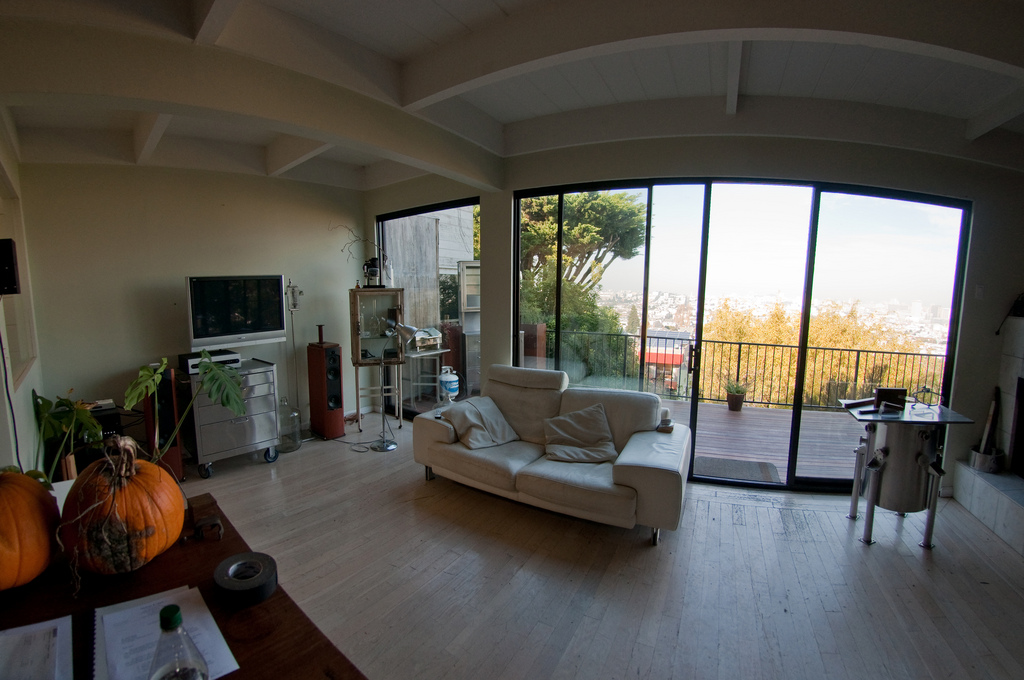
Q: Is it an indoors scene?
A: Yes, it is indoors.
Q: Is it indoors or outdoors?
A: It is indoors.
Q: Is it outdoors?
A: No, it is indoors.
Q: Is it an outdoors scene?
A: No, it is indoors.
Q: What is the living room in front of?
A: The living room is in front of the balcony.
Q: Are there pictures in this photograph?
A: No, there are no pictures.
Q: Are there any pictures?
A: No, there are no pictures.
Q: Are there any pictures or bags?
A: No, there are no pictures or bags.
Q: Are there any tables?
A: Yes, there is a table.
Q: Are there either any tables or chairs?
A: Yes, there is a table.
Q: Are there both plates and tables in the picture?
A: No, there is a table but no plates.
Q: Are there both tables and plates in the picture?
A: No, there is a table but no plates.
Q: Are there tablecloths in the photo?
A: No, there are no tablecloths.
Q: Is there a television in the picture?
A: Yes, there is a television.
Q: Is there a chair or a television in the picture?
A: Yes, there is a television.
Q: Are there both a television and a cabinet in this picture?
A: Yes, there are both a television and a cabinet.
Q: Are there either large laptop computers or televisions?
A: Yes, there is a large television.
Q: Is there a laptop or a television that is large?
A: Yes, the television is large.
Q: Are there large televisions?
A: Yes, there is a large television.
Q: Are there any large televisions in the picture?
A: Yes, there is a large television.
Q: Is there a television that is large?
A: Yes, there is a television that is large.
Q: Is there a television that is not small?
A: Yes, there is a large television.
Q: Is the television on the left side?
A: Yes, the television is on the left of the image.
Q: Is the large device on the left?
A: Yes, the television is on the left of the image.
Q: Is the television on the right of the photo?
A: No, the television is on the left of the image.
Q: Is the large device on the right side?
A: No, the television is on the left of the image.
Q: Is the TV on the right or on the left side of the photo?
A: The TV is on the left of the image.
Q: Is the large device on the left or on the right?
A: The TV is on the left of the image.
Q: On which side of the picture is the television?
A: The television is on the left of the image.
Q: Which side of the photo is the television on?
A: The television is on the left of the image.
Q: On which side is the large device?
A: The television is on the left of the image.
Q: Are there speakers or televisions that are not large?
A: No, there is a television but it is large.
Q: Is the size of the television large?
A: Yes, the television is large.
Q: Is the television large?
A: Yes, the television is large.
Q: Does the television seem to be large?
A: Yes, the television is large.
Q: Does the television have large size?
A: Yes, the television is large.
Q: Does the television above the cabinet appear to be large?
A: Yes, the TV is large.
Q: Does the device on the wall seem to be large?
A: Yes, the TV is large.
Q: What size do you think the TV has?
A: The TV has large size.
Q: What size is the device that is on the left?
A: The TV is large.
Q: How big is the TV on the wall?
A: The TV is large.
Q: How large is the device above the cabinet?
A: The TV is large.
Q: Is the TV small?
A: No, the TV is large.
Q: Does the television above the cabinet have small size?
A: No, the TV is large.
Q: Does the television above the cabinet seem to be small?
A: No, the TV is large.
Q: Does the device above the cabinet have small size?
A: No, the TV is large.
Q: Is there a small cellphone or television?
A: No, there is a television but it is large.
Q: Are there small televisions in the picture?
A: No, there is a television but it is large.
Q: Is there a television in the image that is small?
A: No, there is a television but it is large.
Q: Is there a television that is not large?
A: No, there is a television but it is large.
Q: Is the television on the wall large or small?
A: The TV is large.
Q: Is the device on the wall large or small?
A: The TV is large.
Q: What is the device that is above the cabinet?
A: The device is a television.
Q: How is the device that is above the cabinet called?
A: The device is a television.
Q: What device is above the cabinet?
A: The device is a television.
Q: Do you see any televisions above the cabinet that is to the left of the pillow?
A: Yes, there is a television above the cabinet.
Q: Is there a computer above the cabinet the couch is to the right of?
A: No, there is a television above the cabinet.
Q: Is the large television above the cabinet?
A: Yes, the television is above the cabinet.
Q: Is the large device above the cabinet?
A: Yes, the television is above the cabinet.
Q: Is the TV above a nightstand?
A: No, the TV is above the cabinet.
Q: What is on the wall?
A: The TV is on the wall.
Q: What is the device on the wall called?
A: The device is a television.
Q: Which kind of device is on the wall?
A: The device is a television.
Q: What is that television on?
A: The television is on the wall.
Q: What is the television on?
A: The television is on the wall.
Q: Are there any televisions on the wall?
A: Yes, there is a television on the wall.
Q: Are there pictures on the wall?
A: No, there is a television on the wall.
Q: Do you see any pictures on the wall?
A: No, there is a television on the wall.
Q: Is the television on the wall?
A: Yes, the television is on the wall.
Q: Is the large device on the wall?
A: Yes, the television is on the wall.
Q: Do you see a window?
A: Yes, there is a window.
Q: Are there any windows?
A: Yes, there is a window.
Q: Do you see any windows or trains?
A: Yes, there is a window.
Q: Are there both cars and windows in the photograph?
A: No, there is a window but no cars.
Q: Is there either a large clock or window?
A: Yes, there is a large window.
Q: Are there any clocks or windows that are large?
A: Yes, the window is large.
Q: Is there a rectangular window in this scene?
A: Yes, there is a rectangular window.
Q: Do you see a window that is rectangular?
A: Yes, there is a rectangular window.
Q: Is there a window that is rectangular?
A: Yes, there is a window that is rectangular.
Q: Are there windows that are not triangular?
A: Yes, there is a rectangular window.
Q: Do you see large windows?
A: Yes, there is a large window.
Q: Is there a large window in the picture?
A: Yes, there is a large window.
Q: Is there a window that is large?
A: Yes, there is a window that is large.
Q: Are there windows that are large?
A: Yes, there is a window that is large.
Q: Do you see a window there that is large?
A: Yes, there is a window that is large.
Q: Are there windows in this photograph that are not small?
A: Yes, there is a large window.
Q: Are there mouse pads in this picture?
A: No, there are no mouse pads.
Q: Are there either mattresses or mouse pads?
A: No, there are no mouse pads or mattresses.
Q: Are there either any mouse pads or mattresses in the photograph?
A: No, there are no mouse pads or mattresses.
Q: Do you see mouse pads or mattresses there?
A: No, there are no mouse pads or mattresses.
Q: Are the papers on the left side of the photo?
A: Yes, the papers are on the left of the image.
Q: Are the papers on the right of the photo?
A: No, the papers are on the left of the image.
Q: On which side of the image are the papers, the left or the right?
A: The papers are on the left of the image.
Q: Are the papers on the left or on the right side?
A: The papers are on the left of the image.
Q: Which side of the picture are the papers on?
A: The papers are on the left of the image.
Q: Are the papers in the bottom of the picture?
A: Yes, the papers are in the bottom of the image.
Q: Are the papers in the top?
A: No, the papers are in the bottom of the image.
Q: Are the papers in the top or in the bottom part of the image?
A: The papers are in the bottom of the image.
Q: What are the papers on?
A: The papers are on the table.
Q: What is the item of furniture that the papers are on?
A: The piece of furniture is a table.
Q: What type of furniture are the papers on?
A: The papers are on the table.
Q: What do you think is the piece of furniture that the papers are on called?
A: The piece of furniture is a table.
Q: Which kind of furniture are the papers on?
A: The papers are on the table.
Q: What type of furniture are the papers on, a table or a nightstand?
A: The papers are on a table.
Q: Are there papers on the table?
A: Yes, there are papers on the table.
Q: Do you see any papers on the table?
A: Yes, there are papers on the table.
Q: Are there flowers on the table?
A: No, there are papers on the table.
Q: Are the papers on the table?
A: Yes, the papers are on the table.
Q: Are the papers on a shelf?
A: No, the papers are on the table.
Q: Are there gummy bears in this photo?
A: No, there are no gummy bears.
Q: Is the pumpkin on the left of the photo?
A: Yes, the pumpkin is on the left of the image.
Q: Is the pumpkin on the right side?
A: No, the pumpkin is on the left of the image.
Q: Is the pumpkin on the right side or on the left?
A: The pumpkin is on the left of the image.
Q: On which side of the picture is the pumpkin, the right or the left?
A: The pumpkin is on the left of the image.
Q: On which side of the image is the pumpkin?
A: The pumpkin is on the left of the image.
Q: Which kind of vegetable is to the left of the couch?
A: The vegetable is a pumpkin.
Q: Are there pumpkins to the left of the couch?
A: Yes, there is a pumpkin to the left of the couch.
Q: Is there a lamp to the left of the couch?
A: No, there is a pumpkin to the left of the couch.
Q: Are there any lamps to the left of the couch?
A: No, there is a pumpkin to the left of the couch.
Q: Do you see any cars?
A: No, there are no cars.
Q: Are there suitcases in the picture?
A: No, there are no suitcases.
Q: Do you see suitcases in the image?
A: No, there are no suitcases.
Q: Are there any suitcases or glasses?
A: No, there are no suitcases or glasses.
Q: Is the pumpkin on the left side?
A: Yes, the pumpkin is on the left of the image.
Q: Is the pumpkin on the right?
A: No, the pumpkin is on the left of the image.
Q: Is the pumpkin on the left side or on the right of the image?
A: The pumpkin is on the left of the image.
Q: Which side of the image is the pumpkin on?
A: The pumpkin is on the left of the image.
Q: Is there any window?
A: Yes, there is a window.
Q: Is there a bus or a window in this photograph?
A: Yes, there is a window.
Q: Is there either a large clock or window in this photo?
A: Yes, there is a large window.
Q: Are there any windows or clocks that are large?
A: Yes, the window is large.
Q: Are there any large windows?
A: Yes, there is a large window.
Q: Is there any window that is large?
A: Yes, there is a window that is large.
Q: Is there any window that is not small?
A: Yes, there is a large window.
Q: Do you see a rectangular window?
A: Yes, there is a rectangular window.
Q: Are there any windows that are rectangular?
A: Yes, there is a window that is rectangular.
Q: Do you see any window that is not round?
A: Yes, there is a rectangular window.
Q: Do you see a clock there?
A: No, there are no clocks.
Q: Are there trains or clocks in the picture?
A: No, there are no clocks or trains.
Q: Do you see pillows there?
A: Yes, there is a pillow.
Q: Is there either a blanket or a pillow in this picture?
A: Yes, there is a pillow.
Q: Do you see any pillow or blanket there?
A: Yes, there is a pillow.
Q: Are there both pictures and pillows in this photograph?
A: No, there is a pillow but no pictures.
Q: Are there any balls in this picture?
A: No, there are no balls.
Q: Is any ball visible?
A: No, there are no balls.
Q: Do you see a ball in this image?
A: No, there are no balls.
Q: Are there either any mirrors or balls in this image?
A: No, there are no balls or mirrors.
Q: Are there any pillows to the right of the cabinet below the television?
A: Yes, there is a pillow to the right of the cabinet.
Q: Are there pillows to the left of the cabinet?
A: No, the pillow is to the right of the cabinet.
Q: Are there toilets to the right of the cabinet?
A: No, there is a pillow to the right of the cabinet.